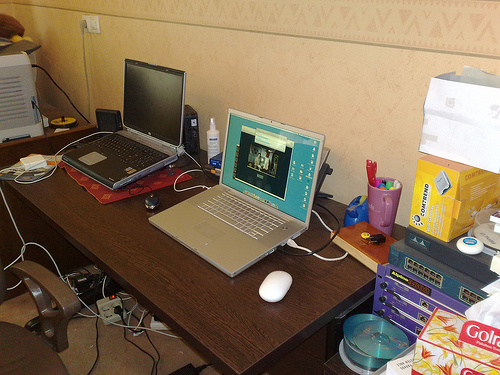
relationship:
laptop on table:
[146, 107, 325, 277] [6, 146, 409, 372]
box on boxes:
[414, 65, 498, 175] [349, 150, 498, 374]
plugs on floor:
[98, 293, 158, 334] [67, 319, 166, 368]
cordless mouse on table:
[253, 268, 297, 305] [1, 123, 375, 370]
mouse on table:
[142, 195, 158, 214] [19, 82, 422, 369]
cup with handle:
[364, 177, 405, 235] [379, 191, 394, 227]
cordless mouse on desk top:
[253, 263, 338, 343] [147, 291, 276, 357]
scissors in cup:
[362, 155, 382, 184] [364, 177, 405, 235]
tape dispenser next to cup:
[342, 194, 359, 222] [364, 177, 405, 235]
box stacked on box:
[406, 163, 498, 237] [388, 235, 495, 308]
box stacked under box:
[406, 163, 498, 237] [416, 77, 498, 174]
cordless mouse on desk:
[253, 268, 297, 305] [59, 114, 353, 346]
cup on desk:
[364, 177, 435, 241] [0, 114, 353, 375]